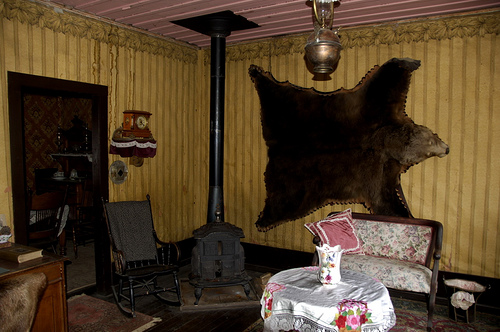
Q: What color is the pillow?
A: Pink and white.